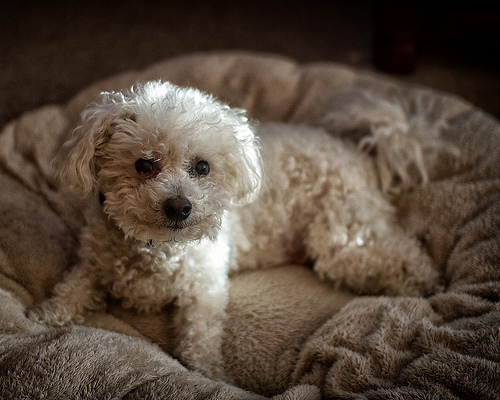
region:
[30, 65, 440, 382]
small and fluffy white dog resting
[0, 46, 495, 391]
dog laying inside tan pet bed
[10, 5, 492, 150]
edge of bed against dark background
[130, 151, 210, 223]
round black eyes over round black nose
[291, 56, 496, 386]
wrinkles and folds along edge of bed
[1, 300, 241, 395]
smooth and curved surface of bed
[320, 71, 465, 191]
strands of tail flopping in every direction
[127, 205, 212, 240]
wide mouth closed in a curve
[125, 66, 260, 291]
light falling over head and leg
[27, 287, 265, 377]
dark seam on bed between paws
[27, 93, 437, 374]
little white dog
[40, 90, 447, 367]
little white puppy with curly hair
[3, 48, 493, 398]
big beige pillow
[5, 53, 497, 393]
small white dog sitting on a beige pillow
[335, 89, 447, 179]
the white dog's tail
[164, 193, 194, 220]
the white dog's black nose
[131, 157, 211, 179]
the white dog's two black eyes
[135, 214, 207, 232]
the white dog's mouth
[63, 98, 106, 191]
the dog's right ear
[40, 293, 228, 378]
the dog's two front paws.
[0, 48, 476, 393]
dog is laying down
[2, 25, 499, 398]
dog is laying on dog bed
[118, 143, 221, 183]
dog's eyes are black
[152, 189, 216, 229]
dog's nose is black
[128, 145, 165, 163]
fur covering dog's eye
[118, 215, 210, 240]
dog's mouth is black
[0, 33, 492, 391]
dog bed is brown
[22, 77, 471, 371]
the dog is white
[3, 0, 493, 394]
dog bed is on floor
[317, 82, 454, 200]
dog's tail touching it's back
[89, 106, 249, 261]
small dog with curly fur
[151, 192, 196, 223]
dog has small nose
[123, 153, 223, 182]
dog with dark eyes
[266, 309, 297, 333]
dog bed is beige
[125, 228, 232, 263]
small beard on dog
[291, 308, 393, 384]
big folds in bed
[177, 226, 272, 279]
sun reflecting off dog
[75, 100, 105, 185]
dog has wavy fur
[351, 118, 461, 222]
dog has fluffy tail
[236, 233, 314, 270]
under belly of dog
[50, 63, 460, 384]
white fluffy dog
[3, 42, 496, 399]
round beige bed dog is laying in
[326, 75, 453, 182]
white fuzzy tail of dog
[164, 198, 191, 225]
black nose of white dog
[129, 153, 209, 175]
brown eyes of white dog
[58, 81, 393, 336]
wavy white hair of dog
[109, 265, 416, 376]
bottom of beige dog bed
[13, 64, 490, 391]
sides of round dog bed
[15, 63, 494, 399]
white dog laying in beige dog bed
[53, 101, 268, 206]
ear of white dog